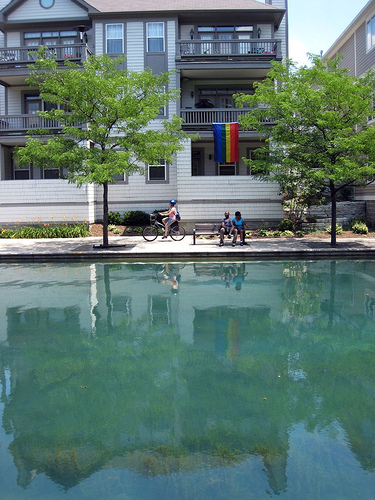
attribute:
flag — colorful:
[212, 123, 237, 162]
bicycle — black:
[143, 215, 185, 239]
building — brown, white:
[2, 1, 292, 226]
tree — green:
[19, 47, 184, 248]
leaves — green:
[123, 91, 159, 116]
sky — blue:
[287, 3, 369, 68]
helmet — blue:
[169, 198, 181, 206]